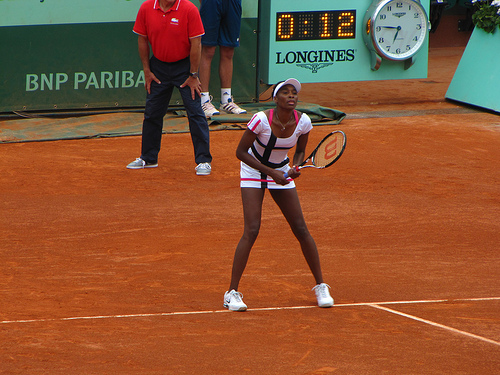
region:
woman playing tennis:
[186, 70, 387, 340]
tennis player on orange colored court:
[47, 159, 457, 345]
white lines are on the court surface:
[36, 305, 446, 350]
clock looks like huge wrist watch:
[366, 1, 427, 73]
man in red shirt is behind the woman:
[121, 2, 201, 76]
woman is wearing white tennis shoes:
[194, 279, 347, 334]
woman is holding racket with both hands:
[271, 156, 312, 193]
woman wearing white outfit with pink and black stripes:
[240, 109, 317, 186]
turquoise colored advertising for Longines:
[266, 38, 386, 78]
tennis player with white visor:
[260, 72, 317, 99]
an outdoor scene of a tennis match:
[0, 1, 498, 374]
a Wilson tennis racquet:
[282, 129, 346, 177]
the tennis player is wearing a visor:
[271, 77, 301, 95]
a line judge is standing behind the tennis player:
[127, 26, 212, 175]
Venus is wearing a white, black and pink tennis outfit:
[239, 112, 311, 188]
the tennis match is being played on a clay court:
[0, 311, 498, 374]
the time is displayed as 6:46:
[270, 0, 426, 80]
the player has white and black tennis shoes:
[221, 288, 246, 309]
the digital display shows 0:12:
[275, 11, 357, 41]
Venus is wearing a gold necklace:
[272, 109, 295, 131]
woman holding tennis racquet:
[302, 135, 354, 171]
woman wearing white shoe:
[217, 280, 250, 313]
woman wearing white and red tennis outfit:
[238, 103, 311, 205]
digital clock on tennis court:
[272, 8, 360, 45]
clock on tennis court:
[371, 2, 433, 69]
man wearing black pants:
[146, 58, 201, 167]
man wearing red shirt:
[136, 6, 198, 53]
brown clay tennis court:
[361, 130, 486, 285]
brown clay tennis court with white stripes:
[339, 260, 486, 367]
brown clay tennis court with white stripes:
[20, 173, 210, 363]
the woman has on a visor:
[260, 57, 329, 115]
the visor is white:
[255, 69, 335, 107]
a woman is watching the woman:
[135, 0, 235, 180]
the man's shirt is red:
[135, 0, 206, 65]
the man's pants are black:
[128, 60, 235, 179]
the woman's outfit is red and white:
[236, 101, 324, 203]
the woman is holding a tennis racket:
[240, 71, 395, 197]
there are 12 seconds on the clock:
[270, 4, 402, 92]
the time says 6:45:
[370, 3, 450, 83]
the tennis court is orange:
[1, 139, 484, 356]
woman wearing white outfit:
[218, 69, 336, 336]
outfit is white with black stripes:
[230, 79, 305, 205]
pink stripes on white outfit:
[232, 107, 339, 209]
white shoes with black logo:
[204, 284, 246, 305]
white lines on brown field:
[285, 285, 466, 337]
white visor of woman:
[254, 79, 326, 119]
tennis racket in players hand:
[282, 134, 353, 178]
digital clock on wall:
[271, 11, 451, 66]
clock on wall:
[357, 4, 447, 66]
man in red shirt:
[111, 16, 282, 173]